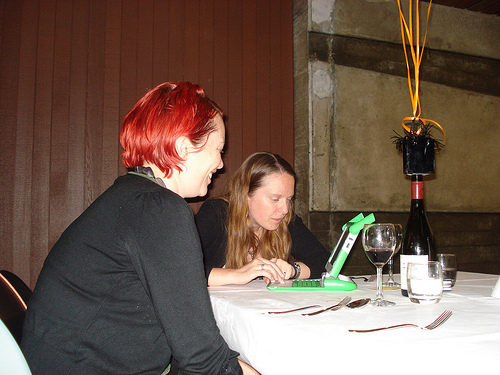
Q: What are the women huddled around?
A: A laptop.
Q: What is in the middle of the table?
A: A wine bottle.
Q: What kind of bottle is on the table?
A: A wine bottle.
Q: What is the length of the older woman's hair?
A: Short.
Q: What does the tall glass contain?
A: Wine.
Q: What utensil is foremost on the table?
A: Fork.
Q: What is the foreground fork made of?
A: Metal.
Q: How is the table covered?
A: With a tablecloth.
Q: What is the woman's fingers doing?
A: Typing.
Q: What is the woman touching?
A: The laptop.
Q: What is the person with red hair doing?
A: Laughing.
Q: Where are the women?
A: At table.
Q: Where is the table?
A: In front of women.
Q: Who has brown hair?
A: One woman.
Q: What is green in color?
A: The laptop.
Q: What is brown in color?
A: The background.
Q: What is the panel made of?
A: Wood.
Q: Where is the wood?
A: In the background of the photo.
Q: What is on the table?
A: A wine glass.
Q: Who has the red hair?
A: A woman.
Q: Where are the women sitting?
A: A table.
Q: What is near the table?
A: Wall.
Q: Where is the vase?
A: On table.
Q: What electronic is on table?
A: Computer.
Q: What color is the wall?
A: Brown.